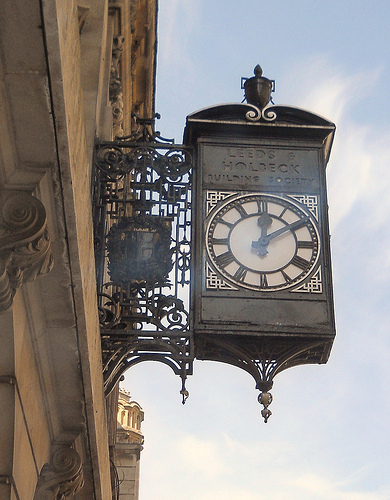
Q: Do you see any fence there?
A: No, there are no fences.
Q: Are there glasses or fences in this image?
A: No, there are no fences or glasses.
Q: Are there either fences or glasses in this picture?
A: No, there are no fences or glasses.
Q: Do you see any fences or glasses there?
A: No, there are no fences or glasses.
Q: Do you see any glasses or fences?
A: No, there are no fences or glasses.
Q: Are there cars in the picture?
A: No, there are no cars.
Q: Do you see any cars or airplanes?
A: No, there are no cars or airplanes.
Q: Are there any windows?
A: Yes, there is a window.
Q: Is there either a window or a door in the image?
A: Yes, there is a window.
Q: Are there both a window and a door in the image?
A: No, there is a window but no doors.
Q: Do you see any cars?
A: No, there are no cars.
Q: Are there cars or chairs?
A: No, there are no cars or chairs.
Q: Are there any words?
A: Yes, there are words.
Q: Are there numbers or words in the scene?
A: Yes, there are words.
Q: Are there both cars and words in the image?
A: No, there are words but no cars.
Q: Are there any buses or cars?
A: No, there are no cars or buses.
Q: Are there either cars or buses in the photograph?
A: No, there are no cars or buses.